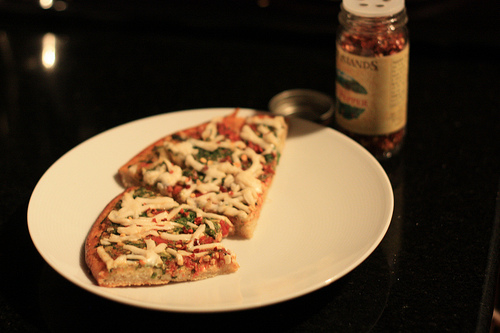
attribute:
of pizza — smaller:
[81, 193, 244, 301]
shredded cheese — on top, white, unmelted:
[96, 195, 220, 268]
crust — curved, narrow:
[80, 181, 131, 275]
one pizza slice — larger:
[112, 100, 315, 205]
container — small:
[331, 0, 442, 157]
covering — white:
[342, 1, 405, 19]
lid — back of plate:
[269, 81, 336, 119]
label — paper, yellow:
[326, 47, 422, 132]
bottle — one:
[330, 1, 414, 161]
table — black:
[6, 5, 264, 99]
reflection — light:
[28, 0, 79, 78]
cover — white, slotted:
[342, 1, 414, 19]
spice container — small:
[334, 16, 418, 160]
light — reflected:
[35, 1, 67, 74]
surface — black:
[122, 21, 259, 104]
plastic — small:
[335, 17, 413, 51]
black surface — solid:
[64, 10, 304, 82]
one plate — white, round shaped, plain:
[22, 101, 396, 309]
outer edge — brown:
[84, 234, 93, 279]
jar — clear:
[335, 11, 412, 53]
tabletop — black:
[61, 14, 271, 97]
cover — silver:
[266, 89, 336, 117]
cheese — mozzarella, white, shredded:
[95, 199, 218, 274]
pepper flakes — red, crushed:
[356, 38, 384, 47]